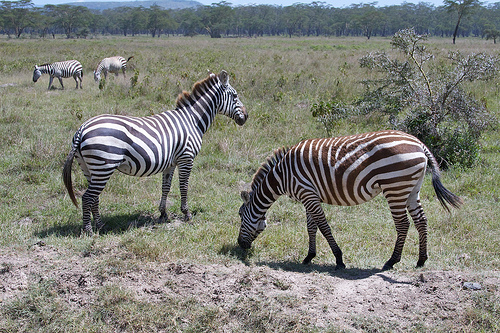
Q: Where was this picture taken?
A: In the wild.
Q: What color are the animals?
A: Black and white.